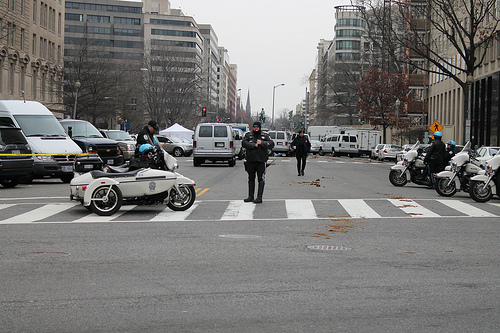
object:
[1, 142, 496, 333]
street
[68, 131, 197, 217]
motorcycle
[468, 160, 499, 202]
motorcycle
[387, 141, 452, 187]
motorcycle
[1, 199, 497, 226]
crosswalk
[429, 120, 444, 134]
sign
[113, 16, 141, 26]
windows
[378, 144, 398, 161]
car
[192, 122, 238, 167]
van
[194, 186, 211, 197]
lines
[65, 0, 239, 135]
buildings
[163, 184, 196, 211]
wheel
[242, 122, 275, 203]
officer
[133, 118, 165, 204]
officer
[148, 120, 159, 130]
hat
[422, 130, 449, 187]
officer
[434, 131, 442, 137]
helmet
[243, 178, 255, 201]
boots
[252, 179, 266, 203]
boots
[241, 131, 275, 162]
jacket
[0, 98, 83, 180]
van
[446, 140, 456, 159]
person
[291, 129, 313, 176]
man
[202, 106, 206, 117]
light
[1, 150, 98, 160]
tape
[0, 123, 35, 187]
car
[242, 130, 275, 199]
uniform